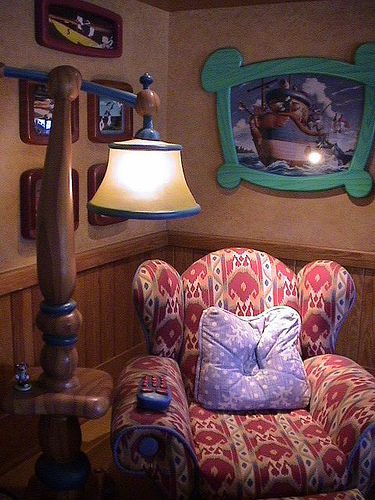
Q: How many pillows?
A: One.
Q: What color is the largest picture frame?
A: Blue.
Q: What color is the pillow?
A: Purple.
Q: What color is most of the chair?
A: Red.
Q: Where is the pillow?
A: On chair.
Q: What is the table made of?
A: Wood.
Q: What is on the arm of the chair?
A: Remote.